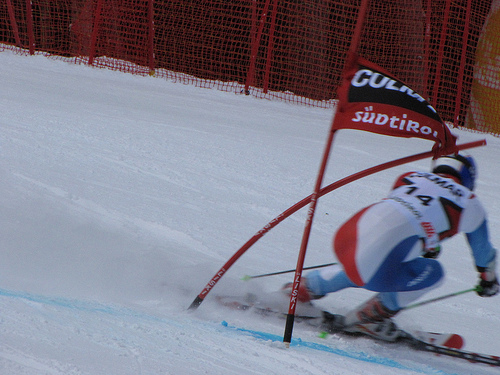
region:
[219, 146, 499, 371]
a person skiing down a snow covered slope.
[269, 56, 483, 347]
a ski flag sticking out of the ground.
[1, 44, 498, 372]
a snow covered ski slope.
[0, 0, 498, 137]
a section of orange mesh.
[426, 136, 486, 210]
the head of a person skiing.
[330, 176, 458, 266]
the back side of a skier.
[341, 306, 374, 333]
the right shoe of a skier.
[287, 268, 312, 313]
the left shoe of a skier.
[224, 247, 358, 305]
a left ski pole.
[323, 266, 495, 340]
a right ski pole.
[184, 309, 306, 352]
blue line in the snow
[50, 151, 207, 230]
tracks in the white snow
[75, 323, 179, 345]
small holes in the snow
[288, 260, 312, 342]
letters on the red pole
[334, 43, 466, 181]
red flag on pole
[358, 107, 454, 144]
white words on red flag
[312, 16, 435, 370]
long red flag in the snow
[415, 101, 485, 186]
red white and blue helmet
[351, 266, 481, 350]
long ski pole in snow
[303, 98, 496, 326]
skier going down hill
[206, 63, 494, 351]
competitive skier on slope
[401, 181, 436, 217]
black number on back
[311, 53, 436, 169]
flag on red pole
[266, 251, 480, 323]
poles in skier's hands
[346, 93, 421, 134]
white word on red flag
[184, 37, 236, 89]
red net of fence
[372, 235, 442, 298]
blue design on uniform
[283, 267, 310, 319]
white letters on pole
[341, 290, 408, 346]
boot on skier foot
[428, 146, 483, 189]
helmet on skier head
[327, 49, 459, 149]
Red, black and white border flag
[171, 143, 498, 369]
Skier leaning into course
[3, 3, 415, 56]
red mesh net in background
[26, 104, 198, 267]
white snow on ground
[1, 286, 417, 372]
aqua blue course guide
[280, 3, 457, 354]
red pole with flag on it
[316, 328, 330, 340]
bright green tip on ski pole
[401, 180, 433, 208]
number 14 on back of skier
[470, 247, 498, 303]
red, white, and black glove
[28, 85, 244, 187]
divets in white snow